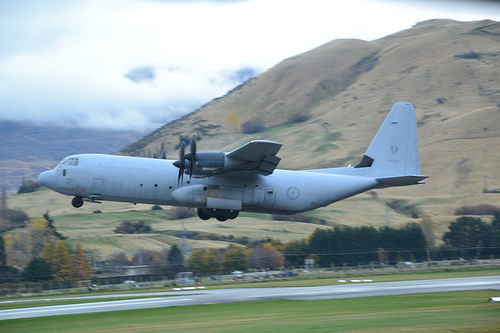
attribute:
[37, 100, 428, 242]
plane — gray, taking off, grey, large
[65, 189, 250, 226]
wheels — retracting, down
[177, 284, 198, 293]
marks — red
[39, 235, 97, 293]
tree — yellow, orange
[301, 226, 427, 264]
trees — green, leafy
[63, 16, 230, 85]
clouds — white, thick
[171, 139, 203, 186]
propellers — gray, grey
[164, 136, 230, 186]
engines — propellers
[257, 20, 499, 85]
mountain — brown, tan, bare, tall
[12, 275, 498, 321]
runway — long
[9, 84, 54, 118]
sky — blue